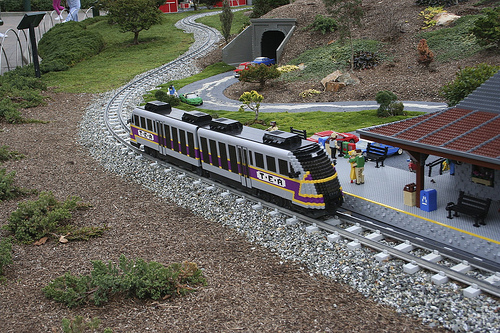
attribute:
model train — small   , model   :
[126, 99, 341, 217]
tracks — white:
[340, 205, 498, 311]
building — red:
[152, 0, 202, 15]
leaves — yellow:
[30, 229, 77, 250]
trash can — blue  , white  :
[415, 180, 441, 214]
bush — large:
[68, 260, 184, 301]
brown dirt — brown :
[8, 87, 418, 330]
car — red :
[224, 56, 251, 85]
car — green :
[176, 90, 203, 109]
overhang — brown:
[356, 105, 499, 169]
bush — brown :
[413, 36, 436, 69]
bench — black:
[362, 139, 392, 169]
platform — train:
[310, 133, 483, 259]